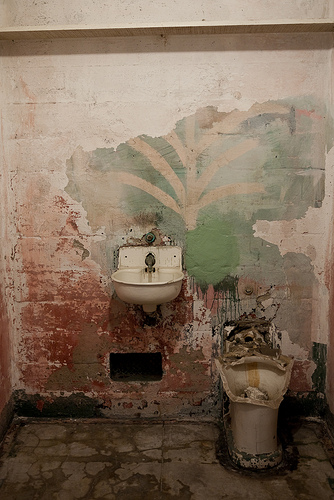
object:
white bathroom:
[0, 35, 334, 345]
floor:
[0, 412, 333, 499]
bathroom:
[0, 35, 332, 500]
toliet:
[214, 315, 295, 471]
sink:
[110, 245, 183, 313]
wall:
[0, 0, 334, 500]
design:
[64, 93, 333, 323]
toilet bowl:
[214, 348, 295, 470]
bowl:
[111, 269, 184, 306]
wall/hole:
[3, 32, 317, 417]